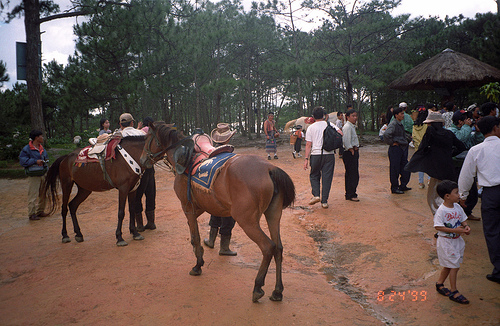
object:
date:
[377, 290, 428, 301]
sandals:
[436, 282, 470, 305]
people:
[341, 109, 359, 202]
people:
[264, 112, 280, 160]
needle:
[125, 32, 132, 38]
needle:
[173, 29, 179, 36]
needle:
[136, 63, 138, 66]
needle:
[109, 16, 119, 23]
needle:
[139, 31, 145, 35]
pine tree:
[0, 0, 500, 148]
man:
[303, 106, 343, 208]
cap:
[399, 102, 408, 108]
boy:
[433, 180, 471, 305]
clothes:
[433, 202, 469, 268]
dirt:
[1, 132, 500, 326]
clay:
[0, 148, 499, 326]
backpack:
[321, 120, 344, 155]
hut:
[387, 47, 500, 102]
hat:
[211, 122, 237, 143]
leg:
[59, 178, 74, 229]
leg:
[68, 182, 92, 234]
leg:
[115, 183, 131, 230]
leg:
[128, 184, 137, 226]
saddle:
[185, 127, 235, 175]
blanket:
[182, 152, 241, 193]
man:
[19, 130, 50, 220]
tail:
[42, 154, 68, 217]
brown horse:
[139, 120, 297, 303]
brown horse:
[41, 129, 146, 247]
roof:
[388, 48, 500, 90]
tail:
[271, 166, 297, 213]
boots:
[29, 211, 49, 220]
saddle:
[89, 128, 123, 160]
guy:
[204, 123, 238, 257]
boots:
[204, 226, 237, 256]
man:
[383, 107, 412, 194]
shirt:
[305, 121, 340, 156]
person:
[404, 109, 467, 216]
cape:
[403, 125, 467, 183]